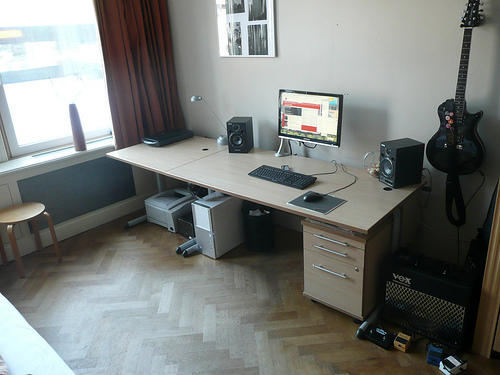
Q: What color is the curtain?
A: Red.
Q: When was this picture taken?
A: Daytime.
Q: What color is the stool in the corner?
A: Brown.